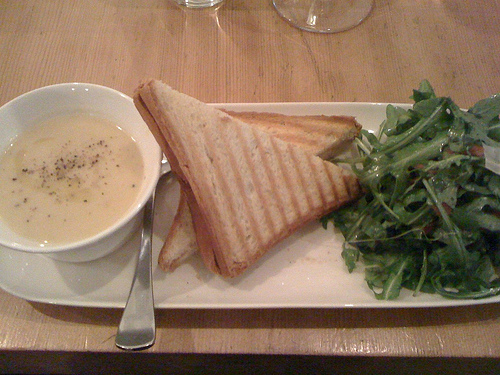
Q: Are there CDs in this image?
A: No, there are no cds.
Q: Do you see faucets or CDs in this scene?
A: No, there are no CDs or faucets.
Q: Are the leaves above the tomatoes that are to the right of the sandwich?
A: Yes, the leaves are above the tomatoes.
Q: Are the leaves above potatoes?
A: No, the leaves are above the tomatoes.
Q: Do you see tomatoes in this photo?
A: Yes, there are tomatoes.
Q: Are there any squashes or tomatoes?
A: Yes, there are tomatoes.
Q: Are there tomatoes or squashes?
A: Yes, there are tomatoes.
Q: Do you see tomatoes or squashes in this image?
A: Yes, there are tomatoes.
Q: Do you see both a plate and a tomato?
A: Yes, there are both a tomato and a plate.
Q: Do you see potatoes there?
A: No, there are no potatoes.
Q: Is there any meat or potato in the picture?
A: No, there are no potatoes or meat.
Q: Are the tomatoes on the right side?
A: Yes, the tomatoes are on the right of the image.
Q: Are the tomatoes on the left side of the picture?
A: No, the tomatoes are on the right of the image.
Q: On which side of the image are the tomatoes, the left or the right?
A: The tomatoes are on the right of the image.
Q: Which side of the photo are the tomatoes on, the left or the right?
A: The tomatoes are on the right of the image.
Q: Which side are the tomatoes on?
A: The tomatoes are on the right of the image.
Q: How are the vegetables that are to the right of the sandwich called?
A: The vegetables are tomatoes.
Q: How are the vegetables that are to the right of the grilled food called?
A: The vegetables are tomatoes.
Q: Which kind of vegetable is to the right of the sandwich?
A: The vegetables are tomatoes.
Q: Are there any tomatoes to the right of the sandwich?
A: Yes, there are tomatoes to the right of the sandwich.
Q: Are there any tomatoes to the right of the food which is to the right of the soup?
A: Yes, there are tomatoes to the right of the sandwich.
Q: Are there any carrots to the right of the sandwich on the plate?
A: No, there are tomatoes to the right of the sandwich.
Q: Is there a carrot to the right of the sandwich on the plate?
A: No, there are tomatoes to the right of the sandwich.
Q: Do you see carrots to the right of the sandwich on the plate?
A: No, there are tomatoes to the right of the sandwich.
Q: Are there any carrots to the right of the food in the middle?
A: No, there are tomatoes to the right of the sandwich.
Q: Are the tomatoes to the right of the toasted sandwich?
A: Yes, the tomatoes are to the right of the sandwich.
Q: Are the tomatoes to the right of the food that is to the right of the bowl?
A: Yes, the tomatoes are to the right of the sandwich.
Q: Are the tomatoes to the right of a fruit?
A: No, the tomatoes are to the right of the sandwich.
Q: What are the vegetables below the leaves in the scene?
A: The vegetables are tomatoes.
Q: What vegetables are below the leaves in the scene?
A: The vegetables are tomatoes.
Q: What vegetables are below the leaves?
A: The vegetables are tomatoes.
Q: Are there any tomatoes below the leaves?
A: Yes, there are tomatoes below the leaves.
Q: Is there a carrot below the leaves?
A: No, there are tomatoes below the leaves.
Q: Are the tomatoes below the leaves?
A: Yes, the tomatoes are below the leaves.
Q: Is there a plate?
A: Yes, there is a plate.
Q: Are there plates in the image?
A: Yes, there is a plate.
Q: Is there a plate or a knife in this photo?
A: Yes, there is a plate.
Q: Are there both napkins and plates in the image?
A: No, there is a plate but no napkins.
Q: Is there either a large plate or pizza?
A: Yes, there is a large plate.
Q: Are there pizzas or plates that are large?
A: Yes, the plate is large.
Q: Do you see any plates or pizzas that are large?
A: Yes, the plate is large.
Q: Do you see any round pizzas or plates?
A: Yes, there is a round plate.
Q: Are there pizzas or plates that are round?
A: Yes, the plate is round.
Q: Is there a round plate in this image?
A: Yes, there is a round plate.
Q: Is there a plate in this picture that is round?
A: Yes, there is a plate that is round.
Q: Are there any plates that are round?
A: Yes, there is a plate that is round.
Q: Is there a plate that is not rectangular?
A: Yes, there is a round plate.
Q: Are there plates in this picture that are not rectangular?
A: Yes, there is a round plate.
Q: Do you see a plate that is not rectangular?
A: Yes, there is a round plate.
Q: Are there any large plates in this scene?
A: Yes, there is a large plate.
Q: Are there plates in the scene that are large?
A: Yes, there is a plate that is large.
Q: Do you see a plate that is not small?
A: Yes, there is a large plate.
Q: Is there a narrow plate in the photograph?
A: Yes, there is a narrow plate.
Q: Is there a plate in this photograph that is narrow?
A: Yes, there is a plate that is narrow.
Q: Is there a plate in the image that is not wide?
A: Yes, there is a narrow plate.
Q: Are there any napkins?
A: No, there are no napkins.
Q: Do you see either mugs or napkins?
A: No, there are no napkins or mugs.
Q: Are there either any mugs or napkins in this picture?
A: No, there are no napkins or mugs.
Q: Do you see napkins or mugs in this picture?
A: No, there are no napkins or mugs.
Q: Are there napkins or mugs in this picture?
A: No, there are no napkins or mugs.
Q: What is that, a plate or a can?
A: That is a plate.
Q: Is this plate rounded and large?
A: Yes, the plate is rounded and large.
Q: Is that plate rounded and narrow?
A: Yes, the plate is rounded and narrow.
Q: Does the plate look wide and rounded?
A: No, the plate is rounded but narrow.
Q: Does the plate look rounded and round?
A: Yes, the plate is rounded and round.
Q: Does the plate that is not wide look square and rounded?
A: No, the plate is rounded but round.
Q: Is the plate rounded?
A: Yes, the plate is rounded.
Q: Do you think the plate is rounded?
A: Yes, the plate is rounded.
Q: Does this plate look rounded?
A: Yes, the plate is rounded.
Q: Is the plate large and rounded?
A: Yes, the plate is large and rounded.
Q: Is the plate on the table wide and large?
A: No, the plate is large but narrow.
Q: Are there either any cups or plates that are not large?
A: No, there is a plate but it is large.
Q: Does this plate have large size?
A: Yes, the plate is large.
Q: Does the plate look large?
A: Yes, the plate is large.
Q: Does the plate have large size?
A: Yes, the plate is large.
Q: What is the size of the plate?
A: The plate is large.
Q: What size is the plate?
A: The plate is large.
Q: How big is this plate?
A: The plate is large.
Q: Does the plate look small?
A: No, the plate is large.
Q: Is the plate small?
A: No, the plate is large.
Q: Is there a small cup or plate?
A: No, there is a plate but it is large.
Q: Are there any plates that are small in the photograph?
A: No, there is a plate but it is large.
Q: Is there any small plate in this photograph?
A: No, there is a plate but it is large.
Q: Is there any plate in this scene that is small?
A: No, there is a plate but it is large.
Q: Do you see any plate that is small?
A: No, there is a plate but it is large.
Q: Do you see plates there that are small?
A: No, there is a plate but it is large.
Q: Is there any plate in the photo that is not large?
A: No, there is a plate but it is large.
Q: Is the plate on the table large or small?
A: The plate is large.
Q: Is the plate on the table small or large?
A: The plate is large.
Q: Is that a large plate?
A: Yes, that is a large plate.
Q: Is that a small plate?
A: No, that is a large plate.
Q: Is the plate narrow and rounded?
A: Yes, the plate is narrow and rounded.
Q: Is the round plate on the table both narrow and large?
A: Yes, the plate is narrow and large.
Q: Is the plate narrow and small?
A: No, the plate is narrow but large.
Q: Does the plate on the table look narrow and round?
A: Yes, the plate is narrow and round.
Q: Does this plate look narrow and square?
A: No, the plate is narrow but round.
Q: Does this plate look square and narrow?
A: No, the plate is narrow but round.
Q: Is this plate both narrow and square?
A: No, the plate is narrow but round.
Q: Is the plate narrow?
A: Yes, the plate is narrow.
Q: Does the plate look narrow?
A: Yes, the plate is narrow.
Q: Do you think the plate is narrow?
A: Yes, the plate is narrow.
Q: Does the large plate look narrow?
A: Yes, the plate is narrow.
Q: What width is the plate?
A: The plate is narrow.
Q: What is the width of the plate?
A: The plate is narrow.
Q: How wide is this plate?
A: The plate is narrow.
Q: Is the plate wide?
A: No, the plate is narrow.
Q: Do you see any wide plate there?
A: No, there is a plate but it is narrow.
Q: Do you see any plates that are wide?
A: No, there is a plate but it is narrow.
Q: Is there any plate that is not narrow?
A: No, there is a plate but it is narrow.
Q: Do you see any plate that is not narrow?
A: No, there is a plate but it is narrow.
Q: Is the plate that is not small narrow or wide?
A: The plate is narrow.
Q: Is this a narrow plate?
A: Yes, this is a narrow plate.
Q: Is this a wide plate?
A: No, this is a narrow plate.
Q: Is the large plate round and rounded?
A: Yes, the plate is round and rounded.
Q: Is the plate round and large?
A: Yes, the plate is round and large.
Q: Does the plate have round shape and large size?
A: Yes, the plate is round and large.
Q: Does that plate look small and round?
A: No, the plate is round but large.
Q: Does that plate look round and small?
A: No, the plate is round but large.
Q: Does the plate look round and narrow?
A: Yes, the plate is round and narrow.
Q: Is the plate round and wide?
A: No, the plate is round but narrow.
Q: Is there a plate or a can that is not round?
A: No, there is a plate but it is round.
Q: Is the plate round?
A: Yes, the plate is round.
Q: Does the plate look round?
A: Yes, the plate is round.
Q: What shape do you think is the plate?
A: The plate is round.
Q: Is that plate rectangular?
A: No, the plate is round.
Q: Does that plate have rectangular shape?
A: No, the plate is round.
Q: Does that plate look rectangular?
A: No, the plate is round.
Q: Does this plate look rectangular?
A: No, the plate is round.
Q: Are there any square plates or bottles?
A: No, there is a plate but it is round.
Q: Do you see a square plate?
A: No, there is a plate but it is round.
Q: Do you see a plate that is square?
A: No, there is a plate but it is round.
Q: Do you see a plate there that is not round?
A: No, there is a plate but it is round.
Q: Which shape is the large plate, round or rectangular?
A: The plate is round.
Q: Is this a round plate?
A: Yes, this is a round plate.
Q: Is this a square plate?
A: No, this is a round plate.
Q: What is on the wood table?
A: The plate is on the table.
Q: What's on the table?
A: The plate is on the table.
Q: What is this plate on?
A: The plate is on the table.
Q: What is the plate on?
A: The plate is on the table.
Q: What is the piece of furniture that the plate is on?
A: The piece of furniture is a table.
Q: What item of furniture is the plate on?
A: The plate is on the table.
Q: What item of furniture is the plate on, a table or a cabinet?
A: The plate is on a table.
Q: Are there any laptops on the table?
A: No, there is a plate on the table.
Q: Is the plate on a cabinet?
A: No, the plate is on a table.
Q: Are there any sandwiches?
A: Yes, there is a sandwich.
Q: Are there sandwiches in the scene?
A: Yes, there is a sandwich.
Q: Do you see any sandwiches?
A: Yes, there is a sandwich.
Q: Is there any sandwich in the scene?
A: Yes, there is a sandwich.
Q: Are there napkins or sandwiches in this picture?
A: Yes, there is a sandwich.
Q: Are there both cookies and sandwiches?
A: No, there is a sandwich but no cookies.